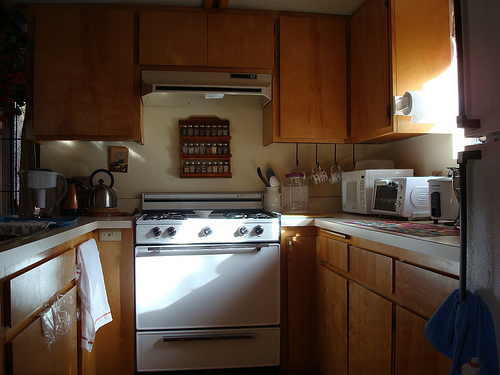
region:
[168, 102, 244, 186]
spice shelf attached over stove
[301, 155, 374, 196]
coffee mugs hanging under cabinet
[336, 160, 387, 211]
white microwave on counter top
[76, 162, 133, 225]
stainless steel kettle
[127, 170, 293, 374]
white stove with black knobs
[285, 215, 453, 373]
wooden cabinets under counter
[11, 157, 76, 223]
reuseable water pitcher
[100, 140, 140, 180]
framed picture hanging on wall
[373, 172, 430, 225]
white toaster oven on counter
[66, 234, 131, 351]
white kitchen dish towel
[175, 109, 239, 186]
rack filled with spices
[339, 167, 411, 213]
a white plastic microwave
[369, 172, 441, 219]
a white toaster oven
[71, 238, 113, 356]
white hand towel hanging from a drawer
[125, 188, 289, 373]
gas range painted white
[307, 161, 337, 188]
coffee cup hanging from cabinet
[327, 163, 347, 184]
coffee cup hanging from cabinet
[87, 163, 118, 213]
silver metal tea kettle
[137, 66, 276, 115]
white range hood over range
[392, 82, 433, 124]
end of a paper towel dispenser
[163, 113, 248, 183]
spice rack over stove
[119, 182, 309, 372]
white stove in a kitchen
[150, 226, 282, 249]
knobs on a stove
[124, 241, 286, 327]
oven door on a stove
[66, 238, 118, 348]
towel hanging on a cabinet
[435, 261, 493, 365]
towel hanging on a refrigerator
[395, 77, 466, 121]
paper towel hanging on cabinet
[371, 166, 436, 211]
white toaster oven on cabinet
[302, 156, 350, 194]
coffee mugs hanging on hook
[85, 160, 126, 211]
tea kettle on counter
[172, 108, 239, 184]
Spice rack hanging on wall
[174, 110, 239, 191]
Spice rack is wooden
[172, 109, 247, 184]
Spice rack is brown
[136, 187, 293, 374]
Kitchen range is white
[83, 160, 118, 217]
Silver kettle on counter top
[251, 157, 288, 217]
Spoon caddy on countertop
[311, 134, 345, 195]
Coffee cups hanging from cabinet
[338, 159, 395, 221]
Microwave sitting on counter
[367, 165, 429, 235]
Toaster oven sitting on counter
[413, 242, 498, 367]
Dish towel is blue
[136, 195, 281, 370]
White electric range with oven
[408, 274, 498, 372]
Blue towel on refridgerator handle.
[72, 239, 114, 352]
White towel on cabinet door.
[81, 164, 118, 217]
Silver and black tea kettle.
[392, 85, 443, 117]
Paper towel on dispenser.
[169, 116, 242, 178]
Rack of spices above stove.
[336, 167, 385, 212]
White microwave on counter.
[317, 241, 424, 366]
Light beige kitchen cabinets.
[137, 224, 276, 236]
Control knobs on white range.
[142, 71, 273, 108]
Overhead range hood vent.